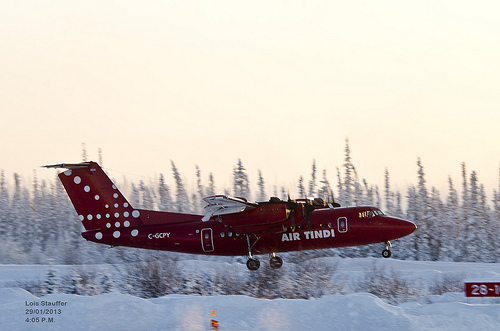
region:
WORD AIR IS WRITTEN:
[289, 228, 300, 247]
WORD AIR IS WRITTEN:
[279, 237, 290, 244]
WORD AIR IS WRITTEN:
[281, 235, 291, 239]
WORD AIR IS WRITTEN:
[284, 234, 296, 245]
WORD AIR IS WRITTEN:
[287, 231, 294, 248]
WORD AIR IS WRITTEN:
[294, 230, 300, 251]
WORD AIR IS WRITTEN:
[283, 219, 302, 260]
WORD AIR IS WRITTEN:
[286, 216, 298, 249]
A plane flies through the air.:
[26, 148, 422, 284]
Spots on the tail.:
[50, 154, 149, 247]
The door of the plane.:
[199, 224, 216, 254]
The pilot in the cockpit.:
[356, 207, 383, 223]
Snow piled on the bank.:
[239, 291, 494, 329]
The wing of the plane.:
[191, 190, 280, 234]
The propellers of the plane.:
[278, 191, 317, 232]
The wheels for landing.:
[245, 246, 405, 288]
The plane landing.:
[38, 149, 426, 278]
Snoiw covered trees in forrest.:
[418, 159, 498, 276]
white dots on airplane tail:
[129, 207, 141, 217]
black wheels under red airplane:
[246, 256, 261, 271]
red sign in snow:
[463, 279, 498, 301]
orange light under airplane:
[211, 307, 219, 329]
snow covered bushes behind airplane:
[24, 246, 471, 301]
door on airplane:
[200, 227, 216, 254]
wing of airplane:
[201, 195, 251, 227]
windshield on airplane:
[372, 207, 384, 216]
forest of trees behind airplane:
[1, 143, 496, 260]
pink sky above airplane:
[2, 1, 497, 198]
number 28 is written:
[477, 278, 484, 297]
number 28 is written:
[474, 280, 484, 310]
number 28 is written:
[465, 274, 477, 309]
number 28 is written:
[473, 280, 483, 293]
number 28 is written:
[482, 288, 492, 297]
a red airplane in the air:
[25, 149, 451, 287]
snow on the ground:
[14, 253, 498, 320]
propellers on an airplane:
[263, 179, 420, 266]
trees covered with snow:
[317, 139, 499, 299]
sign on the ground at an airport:
[457, 269, 499, 314]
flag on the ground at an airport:
[192, 302, 237, 329]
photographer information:
[15, 295, 71, 330]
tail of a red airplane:
[40, 152, 181, 264]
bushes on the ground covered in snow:
[32, 244, 469, 303]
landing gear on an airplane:
[222, 234, 424, 285]